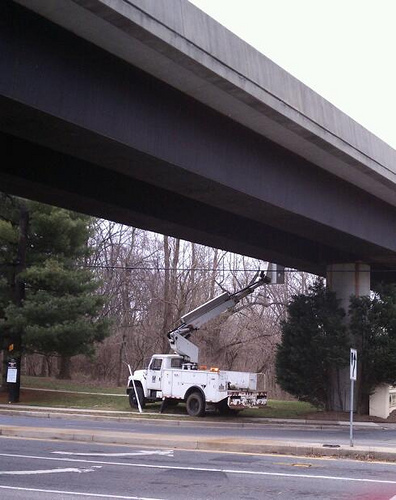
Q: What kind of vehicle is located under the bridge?
A: A utility crane.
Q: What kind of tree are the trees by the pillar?
A: Pine trees.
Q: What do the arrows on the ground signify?
A: Left turn only.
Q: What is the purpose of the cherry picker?
A: To access areas outside of human reach.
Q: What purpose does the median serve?
A: Easing traffic flow.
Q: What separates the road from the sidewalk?
A: Curbs.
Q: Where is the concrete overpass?
A: Over a road.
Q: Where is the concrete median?
A: In a road.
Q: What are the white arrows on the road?
A: Road safety markings.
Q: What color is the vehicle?
A: White.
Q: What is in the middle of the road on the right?
A: Sign.